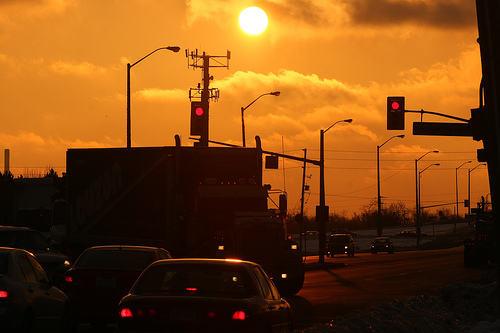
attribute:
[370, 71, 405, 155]
traffic light — red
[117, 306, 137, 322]
brake light — on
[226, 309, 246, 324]
brake light — on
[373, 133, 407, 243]
street light — tall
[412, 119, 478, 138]
street sign — rectangular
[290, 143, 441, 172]
power lines — electric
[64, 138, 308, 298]
truck — large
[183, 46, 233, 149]
tower — cell phone